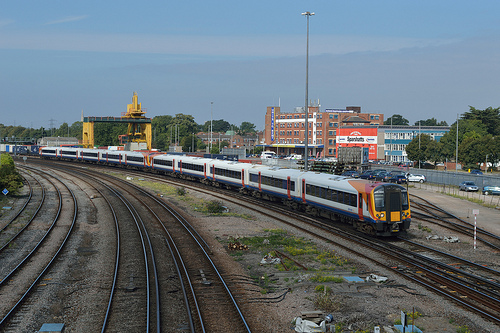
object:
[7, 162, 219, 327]
tracks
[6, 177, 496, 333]
ground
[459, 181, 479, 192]
car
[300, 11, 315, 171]
post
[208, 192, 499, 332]
land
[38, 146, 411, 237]
train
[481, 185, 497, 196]
vehicle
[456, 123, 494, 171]
trees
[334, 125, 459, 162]
buildings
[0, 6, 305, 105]
sky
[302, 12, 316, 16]
light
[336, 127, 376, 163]
sign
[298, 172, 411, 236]
engine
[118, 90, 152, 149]
crane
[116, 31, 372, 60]
clouds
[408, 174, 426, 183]
cars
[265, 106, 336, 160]
house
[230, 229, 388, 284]
litter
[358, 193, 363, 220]
door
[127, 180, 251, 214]
grass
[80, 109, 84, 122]
tower